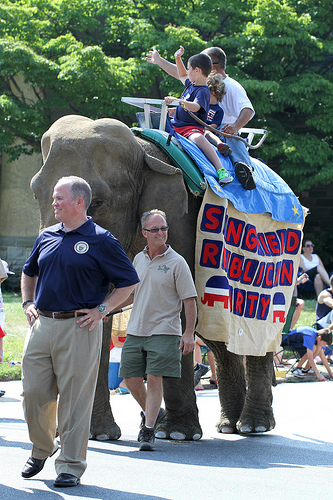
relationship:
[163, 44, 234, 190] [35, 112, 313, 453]
boy riding elephant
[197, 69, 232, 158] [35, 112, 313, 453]
kid riding elephant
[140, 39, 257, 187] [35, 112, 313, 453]
person riding elephant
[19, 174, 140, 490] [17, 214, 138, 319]
man in polo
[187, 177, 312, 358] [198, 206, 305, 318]
sign advertising republican party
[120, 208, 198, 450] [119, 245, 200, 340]
man in polo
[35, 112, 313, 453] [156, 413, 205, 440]
elephant has foot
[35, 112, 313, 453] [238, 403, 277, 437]
elephant has foot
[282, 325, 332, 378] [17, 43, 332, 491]
boy watching parade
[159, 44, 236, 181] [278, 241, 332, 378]
boy waving to crowd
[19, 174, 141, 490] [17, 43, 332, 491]
man in parade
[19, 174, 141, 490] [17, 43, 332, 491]
man walking in parade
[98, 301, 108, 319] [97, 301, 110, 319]
wristwatch on wrist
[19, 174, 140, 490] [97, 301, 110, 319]
man has wrist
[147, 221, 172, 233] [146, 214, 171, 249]
sunglasses on face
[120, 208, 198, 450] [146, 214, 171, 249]
man has face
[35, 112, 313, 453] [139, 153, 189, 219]
elephant has ear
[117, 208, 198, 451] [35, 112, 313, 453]
man leading elephant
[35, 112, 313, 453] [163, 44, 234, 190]
elephant carrying boy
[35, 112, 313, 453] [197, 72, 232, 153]
elephant carrying kid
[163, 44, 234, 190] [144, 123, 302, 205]
boy on back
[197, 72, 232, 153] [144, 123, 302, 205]
kid on back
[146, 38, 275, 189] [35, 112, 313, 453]
family riding elephant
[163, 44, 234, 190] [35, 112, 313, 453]
boy sitting on elephant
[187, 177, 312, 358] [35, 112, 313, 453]
sign over elephant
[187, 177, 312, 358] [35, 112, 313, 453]
sign draped over elephant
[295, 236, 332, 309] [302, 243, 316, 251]
woman with sunglasses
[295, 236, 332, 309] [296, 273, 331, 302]
woman in chair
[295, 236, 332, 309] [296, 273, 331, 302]
woman sitting in chair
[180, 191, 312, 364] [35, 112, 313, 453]
banner on elephant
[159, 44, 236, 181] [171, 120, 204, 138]
boy in shorts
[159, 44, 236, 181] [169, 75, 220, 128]
boy in tee shirt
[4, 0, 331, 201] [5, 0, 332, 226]
leaves on trees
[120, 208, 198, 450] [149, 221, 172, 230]
man wearing glasses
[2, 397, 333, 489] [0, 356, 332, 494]
shadow on pavement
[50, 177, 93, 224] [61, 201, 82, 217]
face with splotches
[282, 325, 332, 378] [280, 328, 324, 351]
boy in tee shirt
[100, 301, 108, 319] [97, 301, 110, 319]
wristwatch on wrist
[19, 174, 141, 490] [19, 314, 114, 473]
man wearing pants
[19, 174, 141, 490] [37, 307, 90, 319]
man wearing belt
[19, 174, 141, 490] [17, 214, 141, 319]
man wearing polo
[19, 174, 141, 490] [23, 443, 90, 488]
man wearing shoes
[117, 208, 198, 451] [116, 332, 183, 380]
man wearing shorts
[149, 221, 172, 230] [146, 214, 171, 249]
glasses on face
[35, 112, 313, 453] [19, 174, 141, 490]
elephant beside man